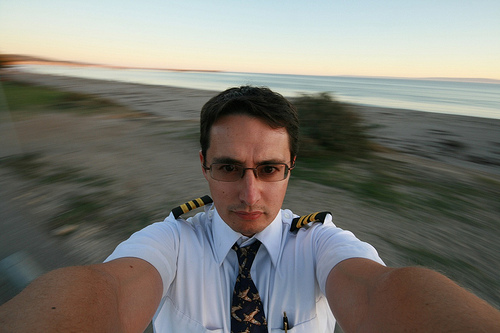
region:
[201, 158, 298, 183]
glasses are in the picture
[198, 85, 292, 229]
glasses are on a face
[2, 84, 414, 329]
man is wearing glasses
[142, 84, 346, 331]
man is wearing a tie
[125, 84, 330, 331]
man has a pen in the shirt pocket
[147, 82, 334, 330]
man has brown hair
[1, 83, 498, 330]
man is in motion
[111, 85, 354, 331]
man is wearing a white shirt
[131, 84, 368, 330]
man in motion is wearing glasses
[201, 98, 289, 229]
right cheek has a mole on it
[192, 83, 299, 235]
the head of a man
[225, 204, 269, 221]
the mouth of a man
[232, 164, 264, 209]
the nose of a man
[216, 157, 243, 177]
the eye of a man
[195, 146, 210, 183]
the ear of a man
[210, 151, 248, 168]
the eyebrow of a man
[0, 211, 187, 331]
the arm of a man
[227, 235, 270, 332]
a black and brown neck tie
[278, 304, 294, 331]
a pen in the pocket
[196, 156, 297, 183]
a pair of glasses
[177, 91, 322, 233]
a man wearing glasses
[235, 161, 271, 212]
a nose on a face.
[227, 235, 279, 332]
a black and gold neck tie.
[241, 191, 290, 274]
a lapel on a shirt.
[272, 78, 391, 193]
a bush on a beach.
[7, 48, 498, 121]
a body of water near the beach.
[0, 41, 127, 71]
a hillside off in the distance.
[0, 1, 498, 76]
a blue sky after sunset.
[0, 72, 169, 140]
a patch of green grass.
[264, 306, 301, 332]
a pocket protector.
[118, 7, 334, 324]
A man wearing white.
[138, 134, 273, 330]
A man wearing white.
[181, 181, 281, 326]
A man wearing white.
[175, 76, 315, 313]
A man wearing white.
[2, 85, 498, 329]
a spinning man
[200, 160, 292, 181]
glasses on a man's face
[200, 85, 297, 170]
dark brown hair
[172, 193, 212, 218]
striped epaulette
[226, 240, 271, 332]
tie is black and gold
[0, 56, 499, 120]
ocean behind man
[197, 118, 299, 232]
man's face with concerned expression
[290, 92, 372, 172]
a green bush behind the spinning man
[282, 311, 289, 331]
black pen in a shirt pocket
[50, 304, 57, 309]
freckle on right arm of spinning man